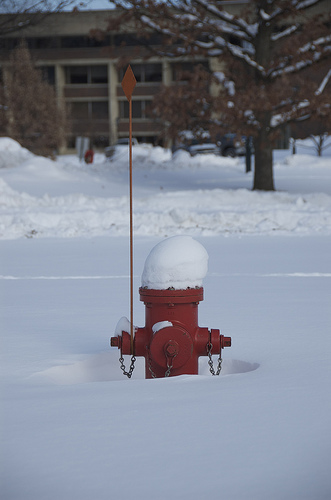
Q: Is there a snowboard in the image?
A: No, there are no snowboards.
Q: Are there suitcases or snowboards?
A: No, there are no snowboards or suitcases.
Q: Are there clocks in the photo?
A: No, there are no clocks.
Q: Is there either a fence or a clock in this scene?
A: No, there are no clocks or fences.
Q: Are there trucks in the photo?
A: Yes, there is a truck.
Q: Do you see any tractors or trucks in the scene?
A: Yes, there is a truck.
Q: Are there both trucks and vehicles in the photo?
A: Yes, there are both a truck and a vehicle.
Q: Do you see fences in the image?
A: No, there are no fences.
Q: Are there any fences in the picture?
A: No, there are no fences.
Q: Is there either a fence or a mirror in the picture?
A: No, there are no fences or mirrors.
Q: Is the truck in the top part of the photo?
A: Yes, the truck is in the top of the image.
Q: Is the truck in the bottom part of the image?
A: No, the truck is in the top of the image.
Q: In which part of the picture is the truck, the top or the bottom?
A: The truck is in the top of the image.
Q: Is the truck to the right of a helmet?
A: No, the truck is to the right of the vehicle.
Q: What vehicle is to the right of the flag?
A: The vehicle is a truck.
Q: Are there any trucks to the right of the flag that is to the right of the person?
A: Yes, there is a truck to the right of the flag.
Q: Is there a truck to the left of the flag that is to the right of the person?
A: No, the truck is to the right of the flag.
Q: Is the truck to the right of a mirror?
A: No, the truck is to the right of the flag.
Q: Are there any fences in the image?
A: No, there are no fences.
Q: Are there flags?
A: Yes, there is a flag.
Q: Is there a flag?
A: Yes, there is a flag.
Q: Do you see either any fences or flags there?
A: Yes, there is a flag.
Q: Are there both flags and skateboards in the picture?
A: No, there is a flag but no skateboards.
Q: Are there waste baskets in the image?
A: No, there are no waste baskets.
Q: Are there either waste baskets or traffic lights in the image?
A: No, there are no waste baskets or traffic lights.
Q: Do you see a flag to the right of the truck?
A: No, the flag is to the left of the truck.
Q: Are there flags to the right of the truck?
A: No, the flag is to the left of the truck.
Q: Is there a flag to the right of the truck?
A: No, the flag is to the left of the truck.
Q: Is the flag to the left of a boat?
A: No, the flag is to the left of a truck.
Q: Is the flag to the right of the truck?
A: No, the flag is to the left of the truck.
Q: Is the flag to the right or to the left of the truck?
A: The flag is to the left of the truck.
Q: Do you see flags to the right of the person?
A: Yes, there is a flag to the right of the person.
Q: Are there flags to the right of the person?
A: Yes, there is a flag to the right of the person.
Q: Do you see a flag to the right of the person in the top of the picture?
A: Yes, there is a flag to the right of the person.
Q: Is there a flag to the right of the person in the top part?
A: Yes, there is a flag to the right of the person.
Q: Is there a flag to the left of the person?
A: No, the flag is to the right of the person.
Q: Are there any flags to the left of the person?
A: No, the flag is to the right of the person.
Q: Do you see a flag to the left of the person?
A: No, the flag is to the right of the person.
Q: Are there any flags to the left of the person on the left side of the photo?
A: No, the flag is to the right of the person.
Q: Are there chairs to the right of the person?
A: No, there is a flag to the right of the person.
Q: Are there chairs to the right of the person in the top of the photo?
A: No, there is a flag to the right of the person.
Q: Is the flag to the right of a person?
A: Yes, the flag is to the right of a person.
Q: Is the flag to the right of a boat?
A: No, the flag is to the right of a person.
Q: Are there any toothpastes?
A: No, there are no toothpastes.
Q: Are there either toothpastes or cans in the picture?
A: No, there are no toothpastes or cans.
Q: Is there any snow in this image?
A: Yes, there is snow.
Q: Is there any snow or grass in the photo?
A: Yes, there is snow.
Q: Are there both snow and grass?
A: No, there is snow but no grass.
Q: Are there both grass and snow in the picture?
A: No, there is snow but no grass.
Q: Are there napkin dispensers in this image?
A: No, there are no napkin dispensers.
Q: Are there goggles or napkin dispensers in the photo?
A: No, there are no napkin dispensers or goggles.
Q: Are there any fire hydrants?
A: Yes, there is a fire hydrant.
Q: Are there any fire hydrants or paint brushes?
A: Yes, there is a fire hydrant.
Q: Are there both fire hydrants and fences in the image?
A: No, there is a fire hydrant but no fences.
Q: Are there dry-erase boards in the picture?
A: No, there are no dry-erase boards.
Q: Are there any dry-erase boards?
A: No, there are no dry-erase boards.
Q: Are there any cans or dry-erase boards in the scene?
A: No, there are no dry-erase boards or cans.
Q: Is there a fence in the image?
A: No, there are no fences.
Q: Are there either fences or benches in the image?
A: No, there are no fences or benches.